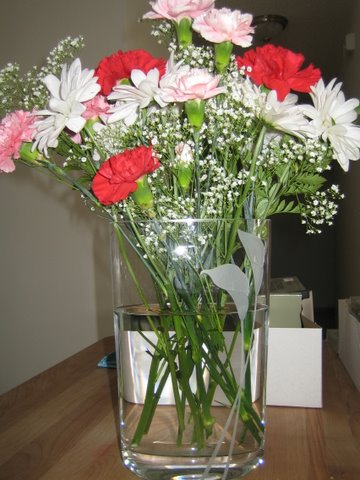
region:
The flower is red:
[239, 49, 318, 99]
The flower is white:
[29, 67, 99, 149]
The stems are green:
[135, 276, 264, 439]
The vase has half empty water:
[108, 222, 262, 472]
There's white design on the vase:
[187, 233, 270, 451]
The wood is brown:
[39, 369, 114, 472]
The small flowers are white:
[207, 168, 244, 218]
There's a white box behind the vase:
[273, 325, 331, 416]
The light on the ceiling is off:
[244, 13, 310, 42]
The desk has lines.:
[281, 418, 354, 469]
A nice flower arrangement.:
[2, 0, 347, 265]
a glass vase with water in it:
[88, 289, 339, 455]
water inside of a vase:
[106, 281, 271, 462]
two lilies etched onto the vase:
[198, 220, 263, 450]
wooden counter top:
[10, 347, 119, 467]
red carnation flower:
[87, 125, 148, 210]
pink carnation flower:
[188, 0, 251, 72]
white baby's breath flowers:
[195, 141, 241, 213]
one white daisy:
[23, 47, 87, 141]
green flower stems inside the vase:
[132, 238, 266, 446]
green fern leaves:
[265, 153, 326, 224]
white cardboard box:
[270, 289, 329, 427]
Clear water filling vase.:
[107, 298, 268, 471]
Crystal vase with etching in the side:
[80, 210, 279, 478]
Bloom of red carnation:
[89, 137, 172, 222]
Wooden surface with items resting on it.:
[1, 330, 356, 479]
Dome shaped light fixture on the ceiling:
[238, 8, 310, 44]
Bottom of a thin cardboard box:
[108, 313, 327, 413]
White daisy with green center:
[300, 78, 359, 175]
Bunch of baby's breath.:
[202, 89, 248, 222]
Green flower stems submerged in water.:
[124, 262, 257, 458]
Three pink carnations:
[157, 1, 254, 142]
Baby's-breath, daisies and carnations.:
[32, 77, 358, 194]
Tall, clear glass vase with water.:
[113, 221, 303, 467]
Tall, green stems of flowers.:
[115, 219, 279, 443]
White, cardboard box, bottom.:
[107, 277, 332, 436]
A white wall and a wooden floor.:
[10, 218, 141, 479]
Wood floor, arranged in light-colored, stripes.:
[12, 385, 105, 478]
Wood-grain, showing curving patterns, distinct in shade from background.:
[17, 384, 97, 448]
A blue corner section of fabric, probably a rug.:
[87, 350, 127, 392]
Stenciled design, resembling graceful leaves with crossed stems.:
[197, 254, 307, 449]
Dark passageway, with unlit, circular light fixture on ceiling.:
[228, 0, 353, 181]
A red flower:
[80, 145, 179, 217]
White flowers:
[275, 92, 358, 176]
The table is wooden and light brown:
[15, 388, 102, 462]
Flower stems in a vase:
[134, 306, 256, 456]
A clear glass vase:
[90, 212, 286, 465]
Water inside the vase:
[93, 286, 295, 477]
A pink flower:
[5, 106, 39, 178]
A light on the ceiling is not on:
[242, 7, 303, 55]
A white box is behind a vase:
[236, 292, 336, 424]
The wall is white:
[20, 237, 84, 315]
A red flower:
[232, 44, 317, 112]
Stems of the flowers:
[134, 279, 267, 449]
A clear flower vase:
[95, 199, 282, 469]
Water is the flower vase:
[90, 278, 292, 458]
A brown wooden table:
[39, 378, 91, 454]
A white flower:
[34, 75, 95, 147]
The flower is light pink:
[190, 5, 257, 61]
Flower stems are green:
[104, 252, 267, 435]